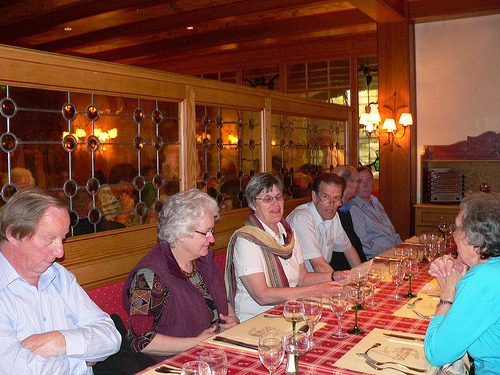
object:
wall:
[374, 22, 417, 239]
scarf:
[223, 214, 295, 309]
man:
[0, 190, 122, 375]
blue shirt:
[423, 257, 500, 374]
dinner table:
[134, 234, 471, 375]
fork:
[363, 354, 429, 374]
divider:
[0, 44, 361, 293]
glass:
[300, 296, 323, 350]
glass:
[328, 287, 350, 338]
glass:
[387, 262, 405, 301]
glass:
[422, 242, 437, 270]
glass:
[257, 333, 285, 375]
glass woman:
[258, 187, 290, 204]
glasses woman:
[121, 188, 241, 364]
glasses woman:
[423, 191, 500, 375]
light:
[359, 111, 414, 151]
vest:
[121, 240, 229, 364]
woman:
[224, 172, 353, 324]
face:
[316, 182, 342, 219]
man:
[285, 172, 362, 273]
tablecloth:
[133, 233, 472, 375]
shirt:
[285, 201, 352, 273]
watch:
[436, 298, 453, 307]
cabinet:
[412, 130, 500, 236]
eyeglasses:
[195, 228, 215, 238]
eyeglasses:
[254, 194, 285, 203]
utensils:
[355, 343, 382, 356]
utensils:
[382, 332, 426, 342]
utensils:
[154, 366, 183, 375]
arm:
[60, 282, 122, 359]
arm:
[126, 281, 194, 358]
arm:
[232, 245, 308, 307]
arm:
[293, 220, 334, 273]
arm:
[333, 215, 362, 268]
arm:
[422, 274, 499, 367]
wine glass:
[402, 257, 419, 298]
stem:
[407, 274, 412, 297]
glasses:
[315, 191, 343, 203]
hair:
[157, 187, 221, 248]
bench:
[84, 251, 236, 337]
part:
[86, 281, 132, 332]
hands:
[427, 255, 467, 295]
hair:
[244, 171, 284, 208]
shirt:
[0, 251, 122, 375]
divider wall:
[2, 45, 362, 302]